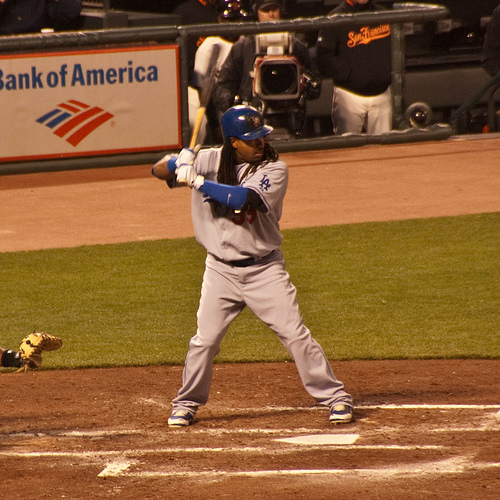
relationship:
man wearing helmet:
[148, 103, 356, 431] [219, 102, 273, 141]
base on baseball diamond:
[267, 431, 362, 446] [2, 372, 494, 493]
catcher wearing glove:
[0, 334, 28, 378] [16, 329, 62, 372]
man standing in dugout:
[315, 0, 396, 137] [3, 3, 448, 167]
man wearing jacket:
[315, 0, 395, 132] [315, 2, 390, 95]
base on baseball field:
[267, 431, 362, 446] [0, 130, 500, 500]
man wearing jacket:
[315, 0, 395, 132] [315, 2, 395, 97]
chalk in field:
[383, 385, 460, 424] [356, 133, 472, 350]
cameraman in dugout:
[219, 2, 327, 135] [15, 7, 497, 170]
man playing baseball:
[151, 109, 351, 426] [32, 318, 220, 376]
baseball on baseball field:
[32, 318, 220, 376] [0, 130, 500, 500]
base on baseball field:
[267, 431, 367, 448] [9, 149, 495, 494]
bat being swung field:
[187, 103, 208, 155] [4, 160, 484, 482]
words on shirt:
[257, 172, 277, 193] [168, 140, 302, 269]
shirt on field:
[168, 140, 302, 269] [4, 160, 484, 482]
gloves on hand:
[167, 150, 207, 191] [173, 141, 209, 194]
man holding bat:
[148, 103, 356, 431] [164, 47, 214, 187]